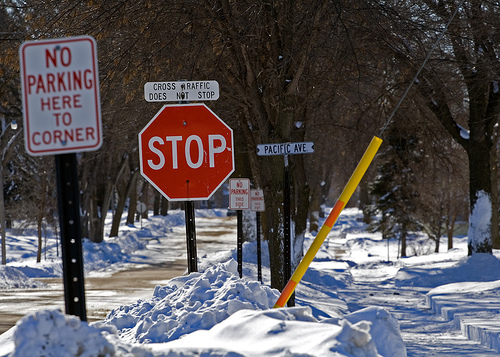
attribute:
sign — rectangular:
[252, 138, 316, 155]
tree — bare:
[1, 23, 163, 248]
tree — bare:
[126, 0, 411, 295]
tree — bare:
[417, 139, 471, 254]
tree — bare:
[368, 115, 441, 259]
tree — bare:
[387, 0, 499, 257]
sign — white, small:
[146, 78, 220, 99]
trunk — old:
[429, 64, 498, 255]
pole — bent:
[273, 124, 410, 338]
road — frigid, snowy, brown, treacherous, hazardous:
[144, 233, 169, 303]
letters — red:
[54, 75, 89, 112]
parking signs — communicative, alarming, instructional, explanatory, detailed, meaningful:
[14, 33, 272, 291]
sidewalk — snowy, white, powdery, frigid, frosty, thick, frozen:
[348, 239, 433, 355]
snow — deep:
[141, 287, 242, 321]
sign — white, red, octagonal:
[141, 105, 246, 210]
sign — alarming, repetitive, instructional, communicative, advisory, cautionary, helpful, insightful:
[18, 35, 103, 317]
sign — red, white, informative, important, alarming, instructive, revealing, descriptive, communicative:
[16, 35, 103, 157]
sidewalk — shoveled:
[312, 206, 489, 349]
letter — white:
[146, 133, 225, 173]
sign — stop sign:
[139, 100, 236, 206]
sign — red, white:
[24, 24, 108, 151]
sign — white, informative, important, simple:
[236, 127, 309, 156]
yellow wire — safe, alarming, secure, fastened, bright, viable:
[290, 113, 402, 322]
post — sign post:
[182, 202, 199, 276]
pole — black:
[179, 199, 199, 273]